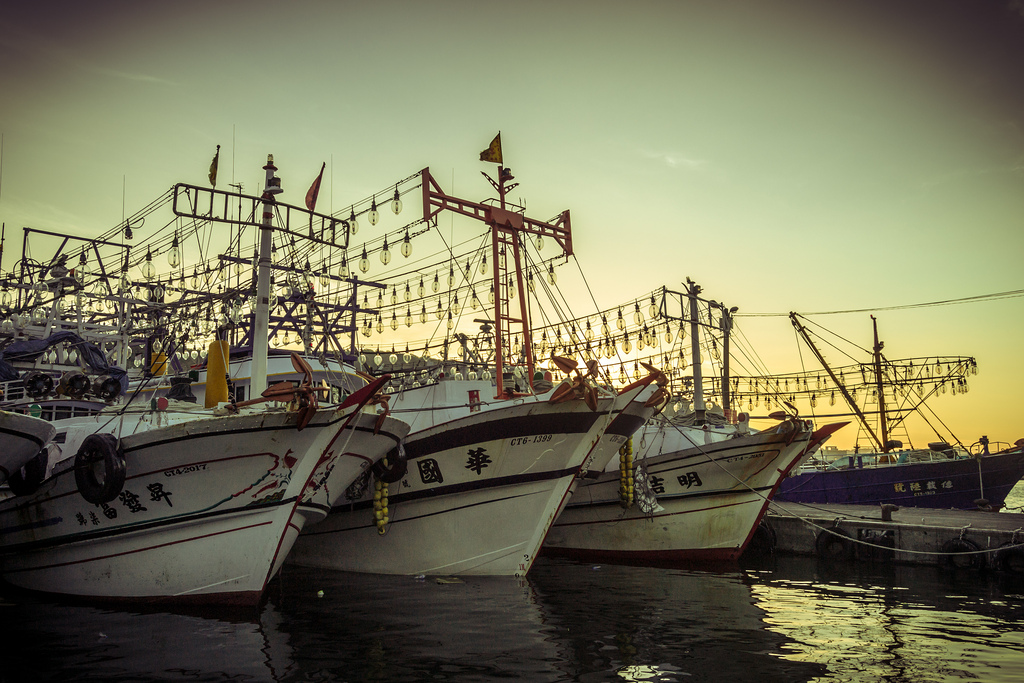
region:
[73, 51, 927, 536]
these are large ships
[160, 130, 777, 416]
the masts are very tall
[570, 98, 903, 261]
the sky is light gray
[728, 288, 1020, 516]
the horizon is yellow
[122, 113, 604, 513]
the lighting is dim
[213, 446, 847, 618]
this is a harbor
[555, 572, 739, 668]
the water is green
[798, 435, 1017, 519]
the far boat is blue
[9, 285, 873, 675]
the boats are white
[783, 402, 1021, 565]
the boat is blue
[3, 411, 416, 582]
lines on the boat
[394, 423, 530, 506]
writing on the boat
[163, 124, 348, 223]
flags on the boat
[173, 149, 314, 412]
a white boat pole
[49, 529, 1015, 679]
the water is dark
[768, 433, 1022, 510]
dark blue and white boat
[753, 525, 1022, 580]
tires hanging on the side of the dock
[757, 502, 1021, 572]
dock in between the boats in the water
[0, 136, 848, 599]
group of white boats in the water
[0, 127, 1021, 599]
collection of boats in the water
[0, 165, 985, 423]
lights hanging over the boats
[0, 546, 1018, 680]
body of calm water with boats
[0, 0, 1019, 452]
open and cloudless sky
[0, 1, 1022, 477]
cloudless sky at dust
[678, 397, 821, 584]
boat in the water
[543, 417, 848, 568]
white boat is next to white boat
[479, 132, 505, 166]
flag flying on boat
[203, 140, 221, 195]
flag flying on boat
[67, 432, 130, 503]
floation device on side of boat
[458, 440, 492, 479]
writing on side of boat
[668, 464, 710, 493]
writing on side of boat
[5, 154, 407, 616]
boat in a marina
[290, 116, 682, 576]
boat in a marina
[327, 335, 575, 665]
a boat int he weater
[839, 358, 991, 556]
a boat in the water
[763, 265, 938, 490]
a pole on the boat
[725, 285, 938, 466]
cables on the boat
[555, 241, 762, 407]
a cable on the boat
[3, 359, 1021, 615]
boats parked in the water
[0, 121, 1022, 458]
wires hanging over the boats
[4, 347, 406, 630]
a boat in the water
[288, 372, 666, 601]
a boat parked in the water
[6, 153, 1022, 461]
a sunset behind the boats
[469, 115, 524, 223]
a flag flapping around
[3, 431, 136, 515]
tires hanging off of the boat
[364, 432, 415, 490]
a tire hanging on the side of the boat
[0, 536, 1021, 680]
water the boats are in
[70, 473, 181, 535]
writing on the boat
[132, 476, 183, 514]
black character on boat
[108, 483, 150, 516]
black character on boat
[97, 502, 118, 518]
black character on boat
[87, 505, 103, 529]
black character on boat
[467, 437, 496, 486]
black character on boat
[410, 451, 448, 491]
black character on boat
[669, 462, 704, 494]
black character on boat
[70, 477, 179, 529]
black characters on boat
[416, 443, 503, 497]
black characters on boat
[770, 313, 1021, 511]
A blue fishing boat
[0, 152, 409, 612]
A boat with oriental writing on the side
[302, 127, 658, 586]
A boat with a thick blue stripe